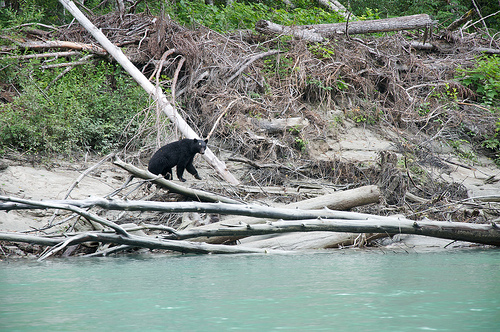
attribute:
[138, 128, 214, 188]
black bear — walking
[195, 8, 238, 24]
bush — green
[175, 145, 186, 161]
bear — black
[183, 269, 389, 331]
water — green, blue, cloudy, calm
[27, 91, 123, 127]
bushes — green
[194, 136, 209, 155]
head — black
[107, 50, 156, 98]
tree trunk — white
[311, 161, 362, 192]
tree limbs — broken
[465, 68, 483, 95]
leaves — green